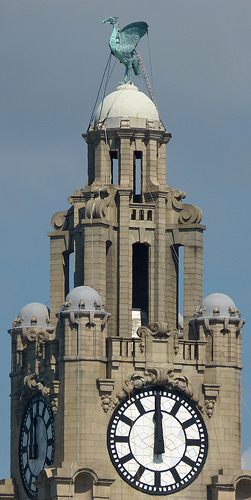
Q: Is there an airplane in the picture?
A: No, there are no airplanes.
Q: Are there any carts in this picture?
A: No, there are no carts.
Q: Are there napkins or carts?
A: No, there are no carts or napkins.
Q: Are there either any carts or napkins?
A: No, there are no carts or napkins.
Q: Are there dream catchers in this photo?
A: No, there are no dream catchers.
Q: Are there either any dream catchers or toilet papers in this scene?
A: No, there are no dream catchers or toilet papers.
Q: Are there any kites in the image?
A: No, there are no kites.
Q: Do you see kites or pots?
A: No, there are no kites or pots.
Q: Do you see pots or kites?
A: No, there are no kites or pots.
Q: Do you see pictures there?
A: No, there are no pictures.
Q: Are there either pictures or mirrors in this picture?
A: No, there are no pictures or mirrors.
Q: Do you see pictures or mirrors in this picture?
A: No, there are no pictures or mirrors.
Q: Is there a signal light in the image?
A: No, there are no traffic lights.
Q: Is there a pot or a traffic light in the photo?
A: No, there are no traffic lights or pots.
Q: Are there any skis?
A: No, there are no skis.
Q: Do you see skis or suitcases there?
A: No, there are no skis or suitcases.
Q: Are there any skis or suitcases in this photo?
A: No, there are no skis or suitcases.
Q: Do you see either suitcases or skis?
A: No, there are no skis or suitcases.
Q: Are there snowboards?
A: No, there are no snowboards.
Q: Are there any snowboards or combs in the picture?
A: No, there are no snowboards or combs.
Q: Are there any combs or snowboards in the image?
A: No, there are no snowboards or combs.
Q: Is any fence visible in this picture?
A: No, there are no fences.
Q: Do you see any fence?
A: No, there are no fences.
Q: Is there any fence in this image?
A: No, there are no fences.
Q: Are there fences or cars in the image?
A: No, there are no fences or cars.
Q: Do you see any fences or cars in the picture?
A: No, there are no fences or cars.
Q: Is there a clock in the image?
A: Yes, there is a clock.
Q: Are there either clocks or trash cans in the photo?
A: Yes, there is a clock.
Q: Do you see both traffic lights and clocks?
A: No, there is a clock but no traffic lights.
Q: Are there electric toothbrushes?
A: No, there are no electric toothbrushes.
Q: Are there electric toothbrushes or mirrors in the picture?
A: No, there are no electric toothbrushes or mirrors.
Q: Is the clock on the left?
A: Yes, the clock is on the left of the image.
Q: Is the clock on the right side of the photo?
A: No, the clock is on the left of the image.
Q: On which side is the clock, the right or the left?
A: The clock is on the left of the image.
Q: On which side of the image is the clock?
A: The clock is on the left of the image.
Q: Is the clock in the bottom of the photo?
A: Yes, the clock is in the bottom of the image.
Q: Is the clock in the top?
A: No, the clock is in the bottom of the image.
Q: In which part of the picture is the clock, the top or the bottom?
A: The clock is in the bottom of the image.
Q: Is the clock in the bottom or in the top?
A: The clock is in the bottom of the image.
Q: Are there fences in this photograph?
A: No, there are no fences.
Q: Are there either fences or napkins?
A: No, there are no fences or napkins.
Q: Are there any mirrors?
A: No, there are no mirrors.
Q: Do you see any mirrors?
A: No, there are no mirrors.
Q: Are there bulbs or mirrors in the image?
A: No, there are no mirrors or bulbs.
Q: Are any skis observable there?
A: No, there are no skis.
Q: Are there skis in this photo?
A: No, there are no skis.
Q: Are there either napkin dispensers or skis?
A: No, there are no skis or napkin dispensers.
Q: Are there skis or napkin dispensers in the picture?
A: No, there are no skis or napkin dispensers.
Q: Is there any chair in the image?
A: No, there are no chairs.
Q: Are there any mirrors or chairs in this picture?
A: No, there are no chairs or mirrors.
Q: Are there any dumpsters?
A: No, there are no dumpsters.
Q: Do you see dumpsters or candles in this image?
A: No, there are no dumpsters or candles.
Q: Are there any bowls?
A: No, there are no bowls.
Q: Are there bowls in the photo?
A: No, there are no bowls.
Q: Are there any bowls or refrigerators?
A: No, there are no bowls or refrigerators.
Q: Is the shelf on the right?
A: Yes, the shelf is on the right of the image.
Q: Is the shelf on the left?
A: No, the shelf is on the right of the image.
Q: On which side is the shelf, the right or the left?
A: The shelf is on the right of the image.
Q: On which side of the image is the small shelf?
A: The shelf is on the right of the image.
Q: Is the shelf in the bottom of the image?
A: Yes, the shelf is in the bottom of the image.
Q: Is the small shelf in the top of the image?
A: No, the shelf is in the bottom of the image.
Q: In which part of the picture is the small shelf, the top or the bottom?
A: The shelf is in the bottom of the image.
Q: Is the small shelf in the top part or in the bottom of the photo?
A: The shelf is in the bottom of the image.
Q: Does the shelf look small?
A: Yes, the shelf is small.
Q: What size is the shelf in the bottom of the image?
A: The shelf is small.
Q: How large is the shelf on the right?
A: The shelf is small.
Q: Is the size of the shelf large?
A: No, the shelf is small.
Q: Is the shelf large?
A: No, the shelf is small.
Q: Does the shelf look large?
A: No, the shelf is small.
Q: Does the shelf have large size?
A: No, the shelf is small.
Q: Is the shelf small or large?
A: The shelf is small.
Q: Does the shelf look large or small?
A: The shelf is small.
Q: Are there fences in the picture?
A: No, there are no fences.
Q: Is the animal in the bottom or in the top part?
A: The animal is in the top of the image.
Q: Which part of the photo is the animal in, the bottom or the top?
A: The animal is in the top of the image.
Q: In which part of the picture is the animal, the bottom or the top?
A: The animal is in the top of the image.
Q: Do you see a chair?
A: No, there are no chairs.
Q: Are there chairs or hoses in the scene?
A: No, there are no chairs or hoses.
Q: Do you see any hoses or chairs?
A: No, there are no chairs or hoses.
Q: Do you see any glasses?
A: No, there are no glasses.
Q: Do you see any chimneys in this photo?
A: No, there are no chimneys.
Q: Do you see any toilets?
A: No, there are no toilets.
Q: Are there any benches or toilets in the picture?
A: No, there are no toilets or benches.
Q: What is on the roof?
A: The dome is on the roof.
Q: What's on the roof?
A: The dome is on the roof.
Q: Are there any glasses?
A: No, there are no glasses.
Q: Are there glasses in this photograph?
A: No, there are no glasses.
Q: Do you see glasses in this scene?
A: No, there are no glasses.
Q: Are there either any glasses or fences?
A: No, there are no glasses or fences.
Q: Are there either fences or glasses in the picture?
A: No, there are no glasses or fences.